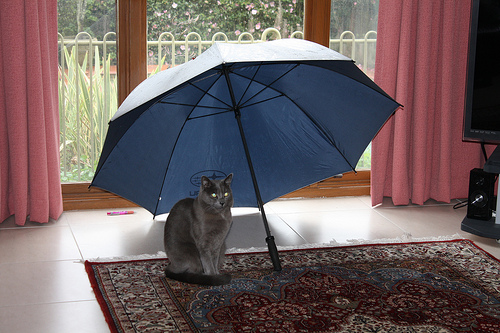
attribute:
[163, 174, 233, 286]
cat — dark grey, gray, furry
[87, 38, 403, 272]
umbrella — opened up, open, inside, blue, white, black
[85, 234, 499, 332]
rug — ornate oriental, red, oriental, patterned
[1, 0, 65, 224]
curtains — long, pink, pinkish red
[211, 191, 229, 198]
eyes — green, glowing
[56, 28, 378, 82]
fence — white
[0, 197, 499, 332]
floor — tiled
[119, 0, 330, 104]
door — class with wood trim, wood framed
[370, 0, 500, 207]
curtain — long, pink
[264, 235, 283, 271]
handle — black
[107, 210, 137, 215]
marker — pink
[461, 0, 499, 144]
television — flat screen, black